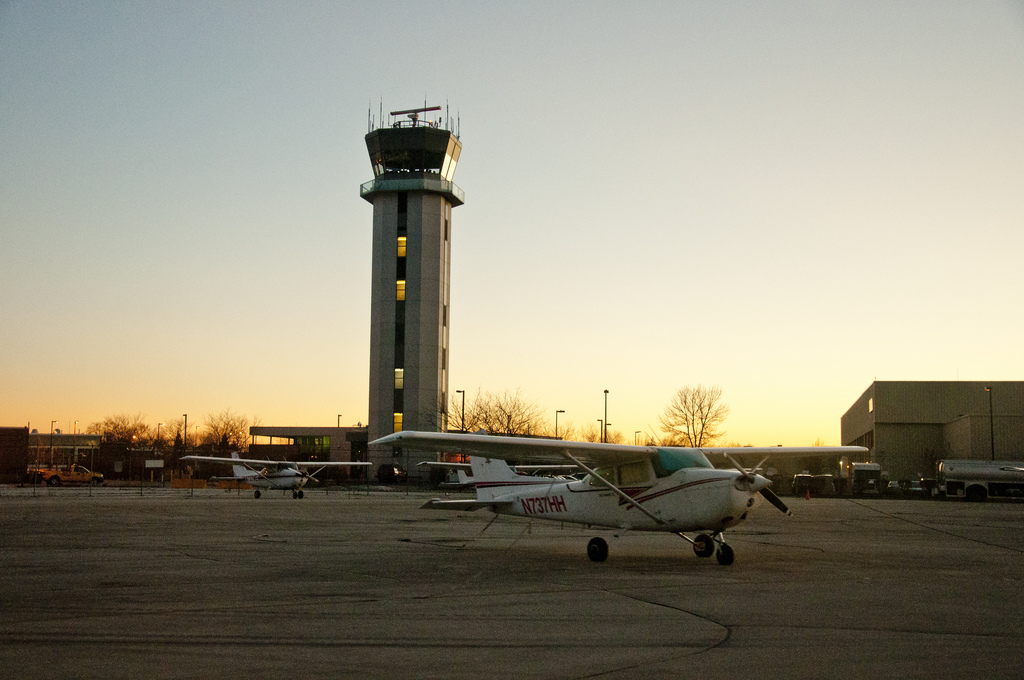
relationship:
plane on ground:
[171, 444, 375, 501] [20, 485, 898, 669]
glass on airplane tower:
[397, 237, 406, 257] [344, 85, 478, 479]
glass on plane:
[651, 448, 713, 478] [337, 407, 869, 582]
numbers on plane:
[512, 485, 579, 518] [335, 387, 887, 599]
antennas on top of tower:
[368, 90, 460, 138] [324, 87, 497, 466]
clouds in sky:
[475, 27, 890, 321] [4, 9, 987, 351]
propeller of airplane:
[728, 446, 791, 516] [369, 404, 780, 552]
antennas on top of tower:
[362, 89, 462, 137] [339, 76, 465, 491]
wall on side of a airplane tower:
[364, 132, 431, 184] [360, 89, 464, 483]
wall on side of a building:
[365, 126, 451, 168] [342, 50, 561, 381]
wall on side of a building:
[346, 65, 498, 448] [360, 154, 408, 247]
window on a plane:
[602, 456, 657, 496] [357, 374, 848, 627]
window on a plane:
[580, 444, 613, 477] [308, 396, 792, 600]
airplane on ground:
[369, 430, 871, 565] [0, 487, 1023, 680]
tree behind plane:
[446, 386, 547, 438] [416, 409, 840, 608]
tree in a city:
[655, 379, 736, 446] [44, 85, 984, 643]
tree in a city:
[454, 385, 548, 427] [44, 85, 984, 643]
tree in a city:
[195, 409, 250, 462] [57, 85, 980, 593]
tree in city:
[660, 383, 730, 448] [20, 384, 1021, 518]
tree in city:
[195, 406, 262, 452] [2, 369, 1022, 495]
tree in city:
[446, 386, 547, 438] [2, 369, 1022, 495]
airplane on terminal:
[368, 428, 869, 565] [17, 369, 1022, 495]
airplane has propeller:
[368, 428, 869, 565] [724, 455, 798, 525]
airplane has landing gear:
[368, 428, 869, 565] [683, 522, 746, 574]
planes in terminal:
[173, 406, 895, 573] [20, 484, 1017, 677]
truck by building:
[925, 451, 1021, 503] [840, 365, 1018, 495]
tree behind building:
[660, 383, 730, 448] [642, 440, 854, 484]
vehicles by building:
[758, 455, 899, 495] [773, 369, 1018, 503]